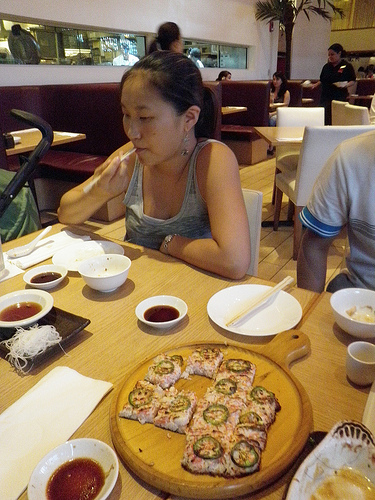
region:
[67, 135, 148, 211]
The woman is holding chopsticks.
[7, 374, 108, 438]
A white napkin on the table.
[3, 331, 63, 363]
Noodles on the corner of plate.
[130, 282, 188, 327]
Soy sauce in a small bowl.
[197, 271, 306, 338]
Chopsticks on the plate.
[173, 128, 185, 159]
The woman is wearing earrings.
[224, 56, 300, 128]
People sitting in the booth.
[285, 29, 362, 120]
A waiter serving food.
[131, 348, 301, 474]
Pizza on a wood board.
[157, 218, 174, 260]
The woman is wearing a watch.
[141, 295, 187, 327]
A bowl of a dark liquid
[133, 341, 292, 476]
A tray of food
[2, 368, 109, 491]
A napkin on the table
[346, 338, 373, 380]
A white cup on the table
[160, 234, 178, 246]
The woman is wearing a watch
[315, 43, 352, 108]
A waitress near the diners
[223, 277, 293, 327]
Chopsticks on the plate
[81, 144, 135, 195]
Chopsticks in the woman's hands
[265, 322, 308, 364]
The handle of the tray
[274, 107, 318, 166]
A white chair by the table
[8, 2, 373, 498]
diners at a restaurant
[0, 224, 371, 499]
Asian style food spread on two tables pushed together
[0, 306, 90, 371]
white noodles on a black dish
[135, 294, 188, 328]
brown liquid in a small white bowl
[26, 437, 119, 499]
dark red liquid in a white bowl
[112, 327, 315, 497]
food cut into slices on a round flat wooden tray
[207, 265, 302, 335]
chopsticks across an otherwise empty white plate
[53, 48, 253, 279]
woman eating from chopsticks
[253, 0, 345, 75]
an artificial-looking palm tree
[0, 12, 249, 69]
kitchen viewed through a long row of windows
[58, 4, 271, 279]
woman eating with chopsticks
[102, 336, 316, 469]
a tray of food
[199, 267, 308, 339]
a plate in the table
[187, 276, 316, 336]
the plate is white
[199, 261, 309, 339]
the plate is round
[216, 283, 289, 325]
shadow of chopsticks on the plate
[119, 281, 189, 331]
small bowl of brown sauce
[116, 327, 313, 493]
the tray is made of wood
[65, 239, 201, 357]
the table is tan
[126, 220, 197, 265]
woman is wearing a watch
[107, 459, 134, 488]
edge of a bowl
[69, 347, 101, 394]
part of a paper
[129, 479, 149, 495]
part of a shade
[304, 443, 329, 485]
prt of a tray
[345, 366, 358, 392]
prt of a cup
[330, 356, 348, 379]
part of a table